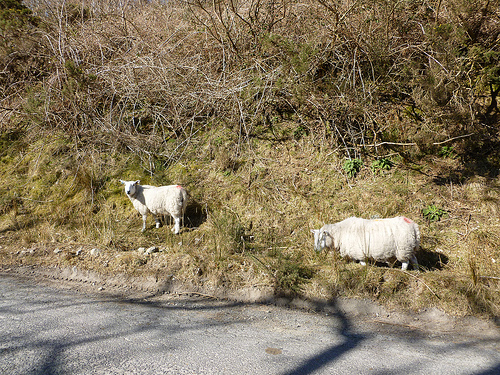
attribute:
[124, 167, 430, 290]
sheep — white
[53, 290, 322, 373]
road — paved, pavd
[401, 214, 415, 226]
mark — red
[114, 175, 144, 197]
face — white